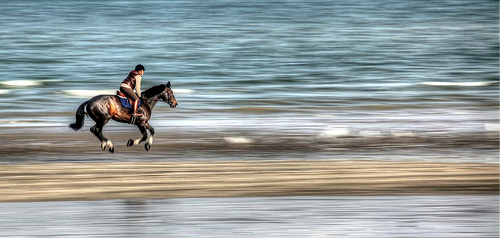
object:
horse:
[66, 80, 179, 153]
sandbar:
[0, 159, 497, 202]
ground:
[0, 162, 500, 236]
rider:
[118, 63, 147, 118]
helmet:
[134, 63, 146, 72]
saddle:
[115, 89, 142, 125]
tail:
[68, 100, 89, 132]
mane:
[135, 83, 165, 94]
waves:
[0, 78, 500, 143]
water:
[0, 0, 500, 160]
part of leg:
[148, 136, 153, 145]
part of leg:
[132, 138, 140, 146]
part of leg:
[106, 140, 114, 148]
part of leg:
[101, 141, 108, 149]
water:
[0, 193, 499, 237]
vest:
[121, 70, 141, 90]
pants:
[119, 86, 140, 100]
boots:
[132, 99, 144, 117]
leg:
[125, 122, 150, 148]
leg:
[89, 118, 110, 151]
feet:
[144, 142, 152, 152]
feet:
[126, 137, 136, 147]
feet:
[108, 147, 116, 154]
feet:
[100, 143, 107, 151]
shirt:
[120, 70, 143, 98]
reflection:
[118, 196, 153, 220]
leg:
[141, 122, 157, 153]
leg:
[94, 118, 115, 153]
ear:
[165, 80, 171, 87]